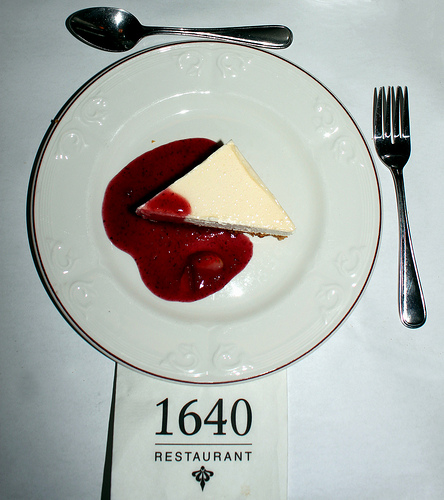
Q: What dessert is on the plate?
A: Cheesecake.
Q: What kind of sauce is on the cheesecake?
A: Strawberry sauce.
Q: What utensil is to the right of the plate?
A: A fork.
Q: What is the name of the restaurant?
A: 1640 RESTAURANT.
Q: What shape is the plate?
A: Round.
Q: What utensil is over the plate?
A: A spoon.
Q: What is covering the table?
A: A white tablecloth.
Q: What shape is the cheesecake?
A: Triangle.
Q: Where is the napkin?
A: On the table slightly under the plate.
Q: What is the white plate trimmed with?
A: Gold.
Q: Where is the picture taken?
A: A restaurant.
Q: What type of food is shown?
A: Desert.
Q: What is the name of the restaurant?
A: 1640.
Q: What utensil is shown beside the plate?
A: A fork.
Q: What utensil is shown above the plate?
A: A spoon.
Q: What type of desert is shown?
A: Cheesecake.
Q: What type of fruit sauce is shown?
A: Strawberry.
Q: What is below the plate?
A: A napkin.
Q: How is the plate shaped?
A: Roundly.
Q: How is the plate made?
A: Of ceramic.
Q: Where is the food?
A: On the plate.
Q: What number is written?
A: 1640.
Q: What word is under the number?
A: Restaurant.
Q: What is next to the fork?
A: Plate.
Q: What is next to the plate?
A: A fork.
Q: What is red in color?
A: The sauce.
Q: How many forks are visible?
A: One.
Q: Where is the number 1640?
A: On the napkin.